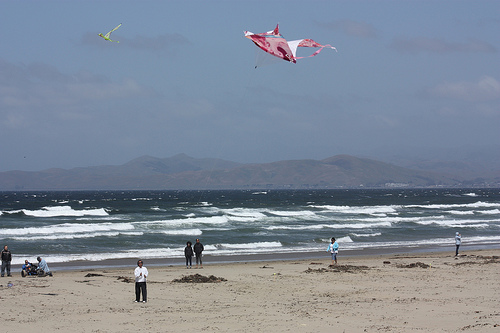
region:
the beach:
[222, 169, 356, 312]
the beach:
[183, 170, 302, 280]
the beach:
[200, 139, 279, 244]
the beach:
[208, 203, 318, 328]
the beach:
[241, 155, 311, 242]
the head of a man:
[136, 255, 146, 267]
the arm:
[131, 269, 141, 281]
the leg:
[133, 280, 140, 300]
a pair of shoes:
[131, 295, 150, 305]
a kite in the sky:
[239, 19, 338, 69]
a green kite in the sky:
[91, 16, 131, 51]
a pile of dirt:
[172, 269, 230, 288]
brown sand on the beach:
[0, 247, 499, 332]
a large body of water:
[1, 190, 499, 261]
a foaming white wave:
[0, 200, 113, 220]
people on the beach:
[0, 210, 495, 302]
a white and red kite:
[222, 24, 376, 95]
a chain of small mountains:
[1, 140, 499, 187]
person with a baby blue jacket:
[321, 239, 345, 254]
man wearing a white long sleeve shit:
[123, 262, 157, 285]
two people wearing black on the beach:
[181, 232, 216, 269]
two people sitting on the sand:
[16, 252, 63, 289]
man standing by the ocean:
[1, 235, 20, 285]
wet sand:
[173, 268, 237, 288]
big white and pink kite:
[232, 19, 339, 75]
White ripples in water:
[33, 198, 421, 265]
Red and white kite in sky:
[227, 25, 342, 76]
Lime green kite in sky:
[91, 17, 135, 49]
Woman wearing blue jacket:
[323, 234, 345, 265]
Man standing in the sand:
[126, 257, 159, 311]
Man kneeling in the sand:
[27, 247, 54, 282]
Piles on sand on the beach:
[168, 266, 231, 292]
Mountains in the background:
[6, 160, 498, 192]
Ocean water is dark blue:
[2, 188, 499, 206]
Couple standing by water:
[178, 230, 206, 272]